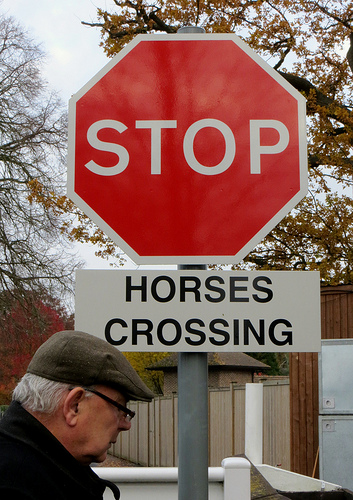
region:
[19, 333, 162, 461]
the head of a person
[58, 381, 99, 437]
the ear of a person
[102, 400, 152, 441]
the nose of a person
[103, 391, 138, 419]
the eye of a person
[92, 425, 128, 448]
the mouth of a person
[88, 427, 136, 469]
the lips of a person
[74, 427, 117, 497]
the chin of a person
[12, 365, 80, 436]
the hair of a person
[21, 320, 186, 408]
a man wearing a hat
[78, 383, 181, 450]
a man wearing glasses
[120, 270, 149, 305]
The letter is black.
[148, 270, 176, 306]
The letter is black.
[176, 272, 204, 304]
The letter is black.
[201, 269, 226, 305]
The letter is black.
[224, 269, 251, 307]
The letter is black.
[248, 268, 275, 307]
The letter is black.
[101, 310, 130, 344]
The letter is black.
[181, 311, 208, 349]
The letter is black.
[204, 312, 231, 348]
The letter is black.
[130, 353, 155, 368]
green leaves on tree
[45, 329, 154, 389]
brown cap on head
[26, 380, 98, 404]
man with white hair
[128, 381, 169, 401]
brim on man's hat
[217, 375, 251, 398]
top of brown fenc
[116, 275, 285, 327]
large black words on white sign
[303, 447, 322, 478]
brown stick leaning against fence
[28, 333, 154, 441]
the head of a man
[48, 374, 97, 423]
the ear of a man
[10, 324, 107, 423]
the hair of a man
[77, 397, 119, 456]
the cheek of a man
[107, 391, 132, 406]
the eye of a man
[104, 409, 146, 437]
the nose of a man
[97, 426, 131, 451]
the lips of a man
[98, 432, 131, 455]
the mouth of a man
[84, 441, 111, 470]
the chin of a man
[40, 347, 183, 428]
a man wearing a hat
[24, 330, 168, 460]
a man wearing eyeglasses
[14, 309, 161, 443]
a man wearing eyeglasses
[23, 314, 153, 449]
a man wearing eyeglasses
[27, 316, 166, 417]
the berret is brown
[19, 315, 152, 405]
the berret is brown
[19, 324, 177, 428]
the berret is brown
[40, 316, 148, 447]
A man with a brown hat on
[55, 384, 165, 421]
A man with dark glasses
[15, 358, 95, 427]
A man with gray hair